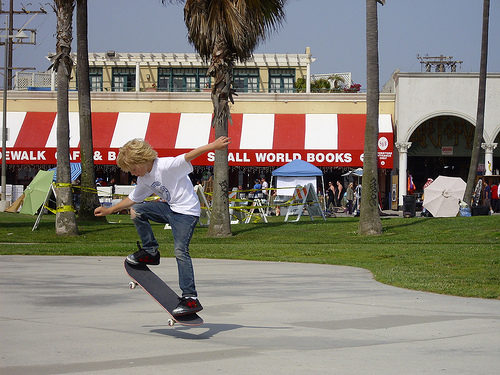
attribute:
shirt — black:
[326, 190, 333, 199]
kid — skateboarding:
[116, 141, 228, 327]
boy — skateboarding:
[94, 126, 235, 335]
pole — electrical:
[3, 1, 45, 88]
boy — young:
[74, 105, 247, 332]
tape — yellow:
[48, 179, 322, 218]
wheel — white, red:
[127, 280, 137, 290]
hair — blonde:
[109, 133, 164, 176]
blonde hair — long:
[116, 137, 158, 177]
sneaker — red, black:
[153, 275, 218, 322]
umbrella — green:
[18, 153, 60, 228]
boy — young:
[94, 135, 231, 314]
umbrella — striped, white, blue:
[50, 158, 84, 185]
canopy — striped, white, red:
[1, 111, 397, 172]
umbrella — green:
[19, 164, 59, 219]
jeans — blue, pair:
[126, 199, 201, 301]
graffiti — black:
[369, 176, 379, 208]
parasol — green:
[18, 168, 53, 216]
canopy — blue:
[264, 157, 330, 218]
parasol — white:
[423, 173, 470, 217]